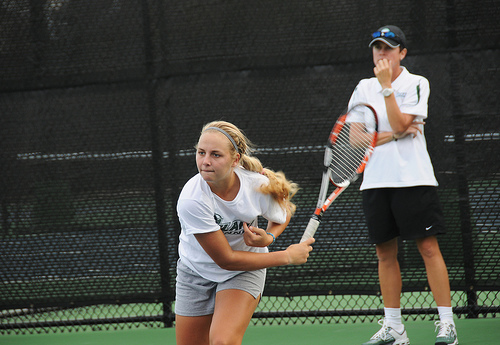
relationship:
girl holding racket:
[173, 121, 315, 344] [284, 95, 380, 268]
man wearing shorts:
[344, 24, 464, 342] [358, 180, 441, 242]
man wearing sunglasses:
[344, 24, 464, 342] [373, 39, 400, 52]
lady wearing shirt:
[174, 120, 316, 344] [174, 166, 295, 278]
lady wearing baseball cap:
[174, 120, 316, 344] [368, 25, 406, 48]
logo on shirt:
[213, 214, 257, 236] [174, 166, 295, 278]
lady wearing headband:
[174, 120, 316, 344] [198, 125, 238, 155]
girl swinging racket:
[173, 121, 315, 344] [298, 103, 379, 246]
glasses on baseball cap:
[368, 30, 398, 42] [368, 25, 406, 48]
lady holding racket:
[174, 120, 316, 344] [300, 103, 377, 242]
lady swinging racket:
[174, 120, 316, 344] [300, 103, 377, 242]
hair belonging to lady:
[198, 118, 300, 219] [174, 120, 316, 344]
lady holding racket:
[172, 117, 314, 343] [298, 103, 379, 246]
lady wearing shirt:
[172, 117, 314, 343] [174, 164, 288, 284]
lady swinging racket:
[172, 117, 314, 343] [298, 103, 379, 246]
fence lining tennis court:
[2, 2, 483, 334] [0, 314, 484, 342]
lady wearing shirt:
[174, 120, 316, 344] [344, 64, 441, 192]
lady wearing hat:
[174, 120, 316, 344] [365, 22, 408, 49]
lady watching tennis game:
[174, 120, 316, 344] [1, 100, 480, 341]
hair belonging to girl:
[198, 118, 300, 219] [171, 116, 314, 343]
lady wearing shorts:
[174, 120, 316, 344] [170, 256, 267, 322]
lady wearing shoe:
[174, 120, 316, 344] [431, 319, 462, 343]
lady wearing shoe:
[174, 120, 316, 344] [357, 315, 411, 343]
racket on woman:
[308, 104, 396, 232] [176, 115, 302, 342]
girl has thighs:
[171, 116, 314, 343] [174, 288, 257, 343]